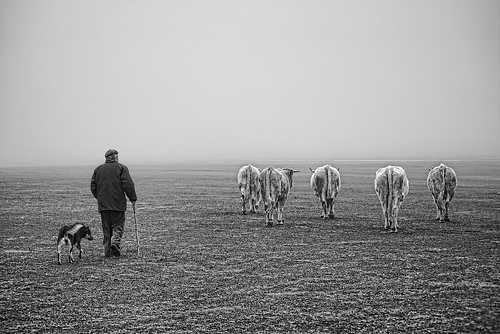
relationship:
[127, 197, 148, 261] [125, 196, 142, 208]
stick in man's hand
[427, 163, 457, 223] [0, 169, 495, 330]
cattle are walking in ground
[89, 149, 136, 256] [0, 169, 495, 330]
man walking in ground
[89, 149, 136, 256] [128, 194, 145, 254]
man holding walking stick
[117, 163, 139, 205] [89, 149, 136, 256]
arm of a man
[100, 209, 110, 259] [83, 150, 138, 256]
leg of man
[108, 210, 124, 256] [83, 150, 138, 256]
leg of man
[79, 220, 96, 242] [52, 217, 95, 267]
head of a dog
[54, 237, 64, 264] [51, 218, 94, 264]
leg of a dog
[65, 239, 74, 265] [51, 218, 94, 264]
leg of a dog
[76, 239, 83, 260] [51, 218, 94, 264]
leg of a dog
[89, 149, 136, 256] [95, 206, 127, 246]
man wearing pants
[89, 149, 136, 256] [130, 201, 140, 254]
man holding stick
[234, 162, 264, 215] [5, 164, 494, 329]
cow in field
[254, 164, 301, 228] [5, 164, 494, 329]
cow in field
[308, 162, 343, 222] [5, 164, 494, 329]
cow in field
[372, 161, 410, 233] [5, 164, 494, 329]
cow in field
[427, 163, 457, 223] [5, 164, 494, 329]
cattle in field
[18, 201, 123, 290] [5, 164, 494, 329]
dog in field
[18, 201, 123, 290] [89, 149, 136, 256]
dog with man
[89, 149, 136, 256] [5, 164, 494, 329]
man in field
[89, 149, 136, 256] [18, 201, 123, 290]
man with dog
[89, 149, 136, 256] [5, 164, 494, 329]
man walking in field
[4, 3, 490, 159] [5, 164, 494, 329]
sky above field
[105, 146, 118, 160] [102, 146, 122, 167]
hat on head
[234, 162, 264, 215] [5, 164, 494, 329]
cow walking in field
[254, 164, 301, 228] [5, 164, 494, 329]
cow walking in field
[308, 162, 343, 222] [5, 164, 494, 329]
cow walking in field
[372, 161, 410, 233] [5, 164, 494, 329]
cow walking in field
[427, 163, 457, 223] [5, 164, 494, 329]
cattle walking in field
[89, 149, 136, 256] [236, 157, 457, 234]
man walking cattle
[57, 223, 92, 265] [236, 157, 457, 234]
dog walking cattle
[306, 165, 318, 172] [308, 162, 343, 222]
horn on cow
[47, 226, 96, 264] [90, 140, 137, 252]
dog by man